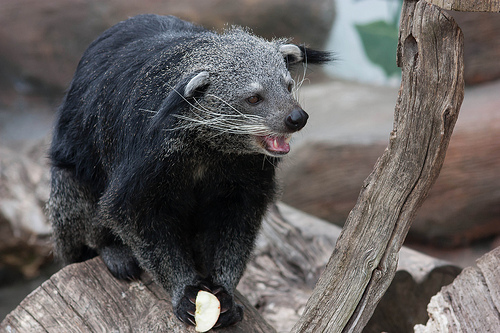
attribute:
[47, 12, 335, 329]
binturong — gray, black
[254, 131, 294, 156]
mouth — open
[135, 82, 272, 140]
whiskers — white, long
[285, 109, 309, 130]
nose — black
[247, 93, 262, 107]
eye — brown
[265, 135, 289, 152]
tongue — pink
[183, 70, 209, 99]
ear — gray, round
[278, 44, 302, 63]
ear — gray, round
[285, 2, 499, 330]
branch — curved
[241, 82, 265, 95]
eyebrow — white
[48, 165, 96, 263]
tail — brushy